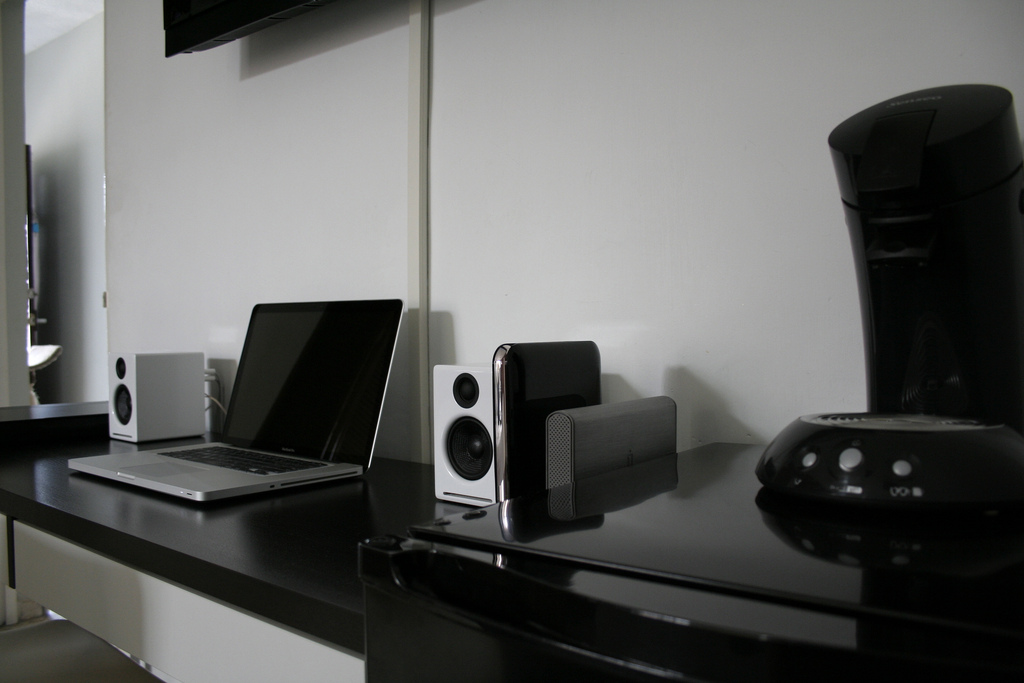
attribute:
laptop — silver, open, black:
[199, 259, 412, 508]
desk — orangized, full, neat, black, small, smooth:
[211, 516, 331, 616]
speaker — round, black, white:
[408, 346, 526, 511]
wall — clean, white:
[468, 23, 691, 201]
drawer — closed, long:
[25, 539, 261, 674]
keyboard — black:
[183, 431, 274, 481]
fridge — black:
[418, 544, 670, 663]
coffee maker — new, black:
[795, 104, 1020, 536]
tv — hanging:
[157, 9, 277, 53]